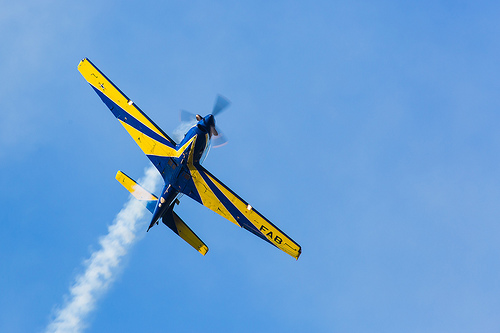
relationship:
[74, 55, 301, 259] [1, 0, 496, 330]
plane in sky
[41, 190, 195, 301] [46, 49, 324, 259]
smoke from plane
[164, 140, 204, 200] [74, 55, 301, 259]
stripe on plane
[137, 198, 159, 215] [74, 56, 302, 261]
stripe on plane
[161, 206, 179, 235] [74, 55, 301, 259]
stripe on plane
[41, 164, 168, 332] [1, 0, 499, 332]
smoke in sky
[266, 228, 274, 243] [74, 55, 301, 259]
black letter on plane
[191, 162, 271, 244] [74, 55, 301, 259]
stripe on plane